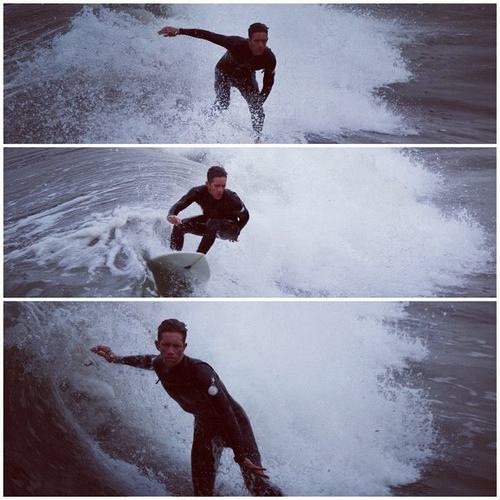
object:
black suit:
[120, 354, 285, 496]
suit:
[175, 26, 277, 143]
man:
[167, 165, 249, 255]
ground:
[353, 145, 388, 185]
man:
[157, 21, 275, 145]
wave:
[0, 144, 500, 304]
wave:
[3, 301, 442, 495]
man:
[89, 317, 284, 494]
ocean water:
[4, 5, 495, 496]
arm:
[117, 354, 157, 370]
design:
[184, 255, 205, 271]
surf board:
[146, 251, 210, 298]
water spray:
[60, 5, 363, 104]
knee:
[205, 217, 220, 231]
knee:
[173, 221, 185, 232]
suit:
[117, 354, 281, 498]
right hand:
[89, 344, 118, 365]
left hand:
[241, 459, 272, 483]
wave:
[4, 10, 491, 140]